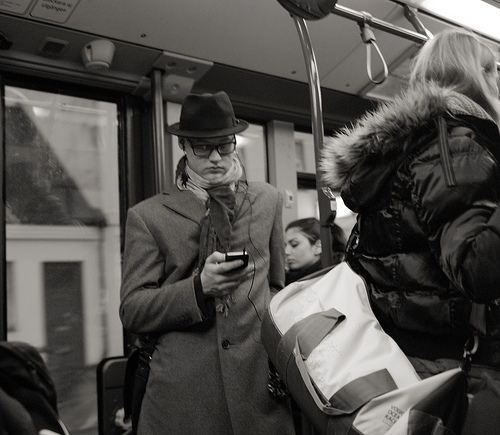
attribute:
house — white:
[1, 89, 111, 372]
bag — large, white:
[270, 268, 435, 433]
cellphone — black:
[220, 248, 253, 260]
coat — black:
[377, 153, 494, 317]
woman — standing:
[326, 19, 496, 273]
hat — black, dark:
[163, 91, 250, 137]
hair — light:
[427, 32, 491, 92]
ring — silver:
[360, 27, 389, 88]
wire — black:
[244, 220, 263, 245]